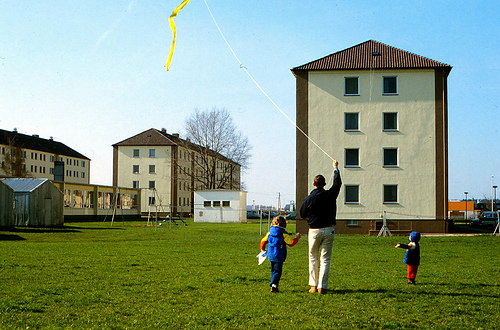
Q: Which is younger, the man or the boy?
A: The boy is younger than the man.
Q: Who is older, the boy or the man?
A: The man is older than the boy.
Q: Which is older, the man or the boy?
A: The man is older than the boy.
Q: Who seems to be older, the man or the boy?
A: The man is older than the boy.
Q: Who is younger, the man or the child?
A: The child is younger than the man.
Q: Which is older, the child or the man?
A: The man is older than the child.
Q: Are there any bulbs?
A: No, there are no bulbs.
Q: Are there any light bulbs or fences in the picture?
A: No, there are no light bulbs or fences.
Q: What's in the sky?
A: The clouds are in the sky.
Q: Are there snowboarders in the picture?
A: No, there are no snowboarders.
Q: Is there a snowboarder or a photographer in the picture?
A: No, there are no snowboarders or photographers.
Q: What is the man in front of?
A: The man is in front of the building.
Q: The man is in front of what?
A: The man is in front of the building.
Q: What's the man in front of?
A: The man is in front of the building.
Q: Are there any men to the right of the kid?
A: Yes, there is a man to the right of the kid.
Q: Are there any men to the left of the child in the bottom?
A: No, the man is to the right of the child.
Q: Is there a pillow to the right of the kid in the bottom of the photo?
A: No, there is a man to the right of the child.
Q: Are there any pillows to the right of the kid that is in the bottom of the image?
A: No, there is a man to the right of the child.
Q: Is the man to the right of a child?
A: Yes, the man is to the right of a child.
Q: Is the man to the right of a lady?
A: No, the man is to the right of a child.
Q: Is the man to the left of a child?
A: No, the man is to the right of a child.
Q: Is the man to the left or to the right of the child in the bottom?
A: The man is to the right of the kid.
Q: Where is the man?
A: The man is on the grass.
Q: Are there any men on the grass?
A: Yes, there is a man on the grass.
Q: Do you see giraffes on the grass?
A: No, there is a man on the grass.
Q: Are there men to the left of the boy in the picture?
A: Yes, there is a man to the left of the boy.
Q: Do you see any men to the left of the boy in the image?
A: Yes, there is a man to the left of the boy.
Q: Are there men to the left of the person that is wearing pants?
A: Yes, there is a man to the left of the boy.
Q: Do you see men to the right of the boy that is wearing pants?
A: No, the man is to the left of the boy.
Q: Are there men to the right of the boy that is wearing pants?
A: No, the man is to the left of the boy.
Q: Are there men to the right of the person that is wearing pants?
A: No, the man is to the left of the boy.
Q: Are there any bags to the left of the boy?
A: No, there is a man to the left of the boy.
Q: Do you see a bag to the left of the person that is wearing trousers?
A: No, there is a man to the left of the boy.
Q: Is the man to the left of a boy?
A: Yes, the man is to the left of a boy.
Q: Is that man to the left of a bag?
A: No, the man is to the left of a boy.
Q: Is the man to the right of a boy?
A: No, the man is to the left of a boy.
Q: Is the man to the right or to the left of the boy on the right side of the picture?
A: The man is to the left of the boy.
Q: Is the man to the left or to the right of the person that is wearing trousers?
A: The man is to the left of the boy.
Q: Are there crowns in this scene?
A: No, there are no crowns.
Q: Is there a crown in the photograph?
A: No, there are no crowns.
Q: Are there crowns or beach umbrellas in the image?
A: No, there are no crowns or beach umbrellas.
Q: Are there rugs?
A: No, there are no rugs.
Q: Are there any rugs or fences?
A: No, there are no rugs or fences.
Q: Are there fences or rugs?
A: No, there are no rugs or fences.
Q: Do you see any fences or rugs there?
A: No, there are no rugs or fences.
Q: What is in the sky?
A: The clouds are in the sky.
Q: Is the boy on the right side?
A: Yes, the boy is on the right of the image.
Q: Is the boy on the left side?
A: No, the boy is on the right of the image.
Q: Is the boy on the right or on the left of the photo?
A: The boy is on the right of the image.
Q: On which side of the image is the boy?
A: The boy is on the right of the image.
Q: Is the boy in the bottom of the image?
A: Yes, the boy is in the bottom of the image.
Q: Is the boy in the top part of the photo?
A: No, the boy is in the bottom of the image.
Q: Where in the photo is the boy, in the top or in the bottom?
A: The boy is in the bottom of the image.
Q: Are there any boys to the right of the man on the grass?
A: Yes, there is a boy to the right of the man.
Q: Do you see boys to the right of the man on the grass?
A: Yes, there is a boy to the right of the man.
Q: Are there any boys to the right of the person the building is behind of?
A: Yes, there is a boy to the right of the man.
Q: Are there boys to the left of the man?
A: No, the boy is to the right of the man.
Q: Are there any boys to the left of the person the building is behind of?
A: No, the boy is to the right of the man.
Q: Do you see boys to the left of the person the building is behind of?
A: No, the boy is to the right of the man.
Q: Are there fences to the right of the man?
A: No, there is a boy to the right of the man.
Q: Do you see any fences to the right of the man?
A: No, there is a boy to the right of the man.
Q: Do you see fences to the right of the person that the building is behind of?
A: No, there is a boy to the right of the man.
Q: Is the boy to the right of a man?
A: Yes, the boy is to the right of a man.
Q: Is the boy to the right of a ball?
A: No, the boy is to the right of a man.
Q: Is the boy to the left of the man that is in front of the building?
A: No, the boy is to the right of the man.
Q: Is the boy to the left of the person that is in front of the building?
A: No, the boy is to the right of the man.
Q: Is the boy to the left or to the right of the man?
A: The boy is to the right of the man.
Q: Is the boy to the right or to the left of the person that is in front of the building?
A: The boy is to the right of the man.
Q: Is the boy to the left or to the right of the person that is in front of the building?
A: The boy is to the right of the man.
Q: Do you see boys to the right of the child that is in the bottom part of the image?
A: Yes, there is a boy to the right of the child.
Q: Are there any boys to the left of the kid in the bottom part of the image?
A: No, the boy is to the right of the kid.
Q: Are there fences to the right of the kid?
A: No, there is a boy to the right of the kid.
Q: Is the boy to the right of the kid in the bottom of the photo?
A: Yes, the boy is to the right of the child.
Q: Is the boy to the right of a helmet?
A: No, the boy is to the right of the child.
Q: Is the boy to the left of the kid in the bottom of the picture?
A: No, the boy is to the right of the kid.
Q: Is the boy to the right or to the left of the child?
A: The boy is to the right of the child.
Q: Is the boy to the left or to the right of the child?
A: The boy is to the right of the child.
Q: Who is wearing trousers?
A: The boy is wearing trousers.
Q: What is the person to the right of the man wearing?
A: The boy is wearing trousers.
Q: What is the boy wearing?
A: The boy is wearing trousers.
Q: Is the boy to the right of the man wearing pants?
A: Yes, the boy is wearing pants.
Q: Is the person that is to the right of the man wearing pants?
A: Yes, the boy is wearing pants.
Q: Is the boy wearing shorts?
A: No, the boy is wearing pants.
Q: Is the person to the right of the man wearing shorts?
A: No, the boy is wearing pants.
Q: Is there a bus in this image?
A: No, there are no buses.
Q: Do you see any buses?
A: No, there are no buses.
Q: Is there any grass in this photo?
A: Yes, there is grass.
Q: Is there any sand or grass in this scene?
A: Yes, there is grass.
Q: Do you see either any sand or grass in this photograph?
A: Yes, there is grass.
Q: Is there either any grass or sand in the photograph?
A: Yes, there is grass.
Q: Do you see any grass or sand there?
A: Yes, there is grass.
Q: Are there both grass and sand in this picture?
A: No, there is grass but no sand.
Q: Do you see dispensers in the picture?
A: No, there are no dispensers.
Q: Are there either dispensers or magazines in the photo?
A: No, there are no dispensers or magazines.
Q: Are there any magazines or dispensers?
A: No, there are no dispensers or magazines.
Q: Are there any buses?
A: No, there are no buses.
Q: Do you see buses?
A: No, there are no buses.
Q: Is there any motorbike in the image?
A: No, there are no motorcycles.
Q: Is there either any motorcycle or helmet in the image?
A: No, there are no motorcycles or helmets.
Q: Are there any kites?
A: Yes, there is a kite.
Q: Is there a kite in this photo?
A: Yes, there is a kite.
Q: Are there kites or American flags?
A: Yes, there is a kite.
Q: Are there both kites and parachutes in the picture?
A: No, there is a kite but no parachutes.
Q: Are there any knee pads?
A: No, there are no knee pads.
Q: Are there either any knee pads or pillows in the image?
A: No, there are no knee pads or pillows.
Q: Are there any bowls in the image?
A: No, there are no bowls.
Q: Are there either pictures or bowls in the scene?
A: No, there are no bowls or pictures.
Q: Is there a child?
A: Yes, there is a child.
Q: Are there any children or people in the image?
A: Yes, there is a child.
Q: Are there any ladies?
A: No, there are no ladies.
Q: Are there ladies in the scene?
A: No, there are no ladies.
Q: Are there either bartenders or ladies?
A: No, there are no ladies or bartenders.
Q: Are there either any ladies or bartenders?
A: No, there are no ladies or bartenders.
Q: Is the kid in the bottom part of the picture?
A: Yes, the kid is in the bottom of the image.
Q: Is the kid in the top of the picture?
A: No, the kid is in the bottom of the image.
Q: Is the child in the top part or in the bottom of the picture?
A: The child is in the bottom of the image.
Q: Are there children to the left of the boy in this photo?
A: Yes, there is a child to the left of the boy.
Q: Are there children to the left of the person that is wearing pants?
A: Yes, there is a child to the left of the boy.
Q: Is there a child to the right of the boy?
A: No, the child is to the left of the boy.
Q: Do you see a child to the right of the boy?
A: No, the child is to the left of the boy.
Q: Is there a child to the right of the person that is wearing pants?
A: No, the child is to the left of the boy.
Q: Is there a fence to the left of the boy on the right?
A: No, there is a child to the left of the boy.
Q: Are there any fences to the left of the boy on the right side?
A: No, there is a child to the left of the boy.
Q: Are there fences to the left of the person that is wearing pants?
A: No, there is a child to the left of the boy.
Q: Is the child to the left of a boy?
A: Yes, the child is to the left of a boy.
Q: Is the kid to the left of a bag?
A: No, the kid is to the left of a boy.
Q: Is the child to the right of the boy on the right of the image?
A: No, the child is to the left of the boy.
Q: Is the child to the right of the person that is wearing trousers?
A: No, the child is to the left of the boy.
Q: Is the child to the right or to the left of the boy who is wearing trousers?
A: The child is to the left of the boy.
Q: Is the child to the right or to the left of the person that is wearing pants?
A: The child is to the left of the boy.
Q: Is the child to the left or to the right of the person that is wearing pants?
A: The child is to the left of the boy.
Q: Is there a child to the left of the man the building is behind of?
A: Yes, there is a child to the left of the man.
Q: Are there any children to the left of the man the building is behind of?
A: Yes, there is a child to the left of the man.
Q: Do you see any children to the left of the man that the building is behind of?
A: Yes, there is a child to the left of the man.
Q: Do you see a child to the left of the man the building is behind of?
A: Yes, there is a child to the left of the man.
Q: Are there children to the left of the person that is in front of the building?
A: Yes, there is a child to the left of the man.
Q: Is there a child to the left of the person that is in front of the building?
A: Yes, there is a child to the left of the man.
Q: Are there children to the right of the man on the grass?
A: No, the child is to the left of the man.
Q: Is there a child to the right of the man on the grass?
A: No, the child is to the left of the man.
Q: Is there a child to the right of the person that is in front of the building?
A: No, the child is to the left of the man.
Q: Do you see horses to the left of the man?
A: No, there is a child to the left of the man.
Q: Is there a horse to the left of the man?
A: No, there is a child to the left of the man.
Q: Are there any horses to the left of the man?
A: No, there is a child to the left of the man.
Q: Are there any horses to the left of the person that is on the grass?
A: No, there is a child to the left of the man.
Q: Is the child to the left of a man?
A: Yes, the child is to the left of a man.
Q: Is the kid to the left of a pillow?
A: No, the kid is to the left of a man.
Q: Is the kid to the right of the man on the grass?
A: No, the kid is to the left of the man.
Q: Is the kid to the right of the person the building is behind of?
A: No, the kid is to the left of the man.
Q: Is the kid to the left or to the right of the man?
A: The kid is to the left of the man.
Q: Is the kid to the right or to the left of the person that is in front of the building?
A: The kid is to the left of the man.